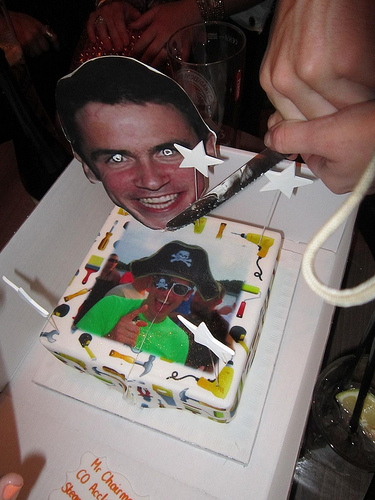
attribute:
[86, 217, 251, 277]
cake — white, decorated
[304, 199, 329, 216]
board — white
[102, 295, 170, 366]
man — smiling, pointing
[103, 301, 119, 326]
shirt — green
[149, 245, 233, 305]
hat — pirate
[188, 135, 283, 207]
stars — white, decoration, close, plastic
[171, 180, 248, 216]
knife — silver, sharp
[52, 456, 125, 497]
writing — orange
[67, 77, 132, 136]
head — cut out, scary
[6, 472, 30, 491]
finger — pointing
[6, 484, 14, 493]
polish — orange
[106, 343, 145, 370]
handle — yellow